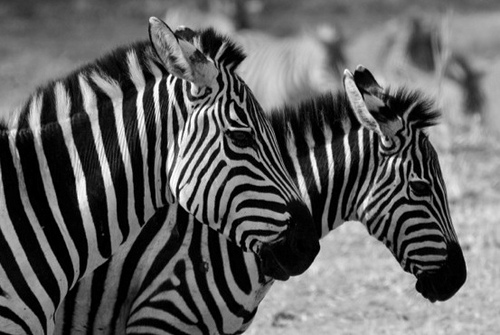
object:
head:
[133, 14, 322, 279]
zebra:
[1, 14, 328, 335]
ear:
[146, 17, 220, 87]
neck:
[0, 91, 181, 328]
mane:
[0, 25, 248, 125]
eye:
[226, 126, 254, 149]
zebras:
[0, 16, 469, 334]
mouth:
[258, 240, 301, 281]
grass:
[242, 66, 499, 303]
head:
[341, 63, 468, 301]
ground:
[310, 285, 391, 326]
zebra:
[313, 65, 465, 301]